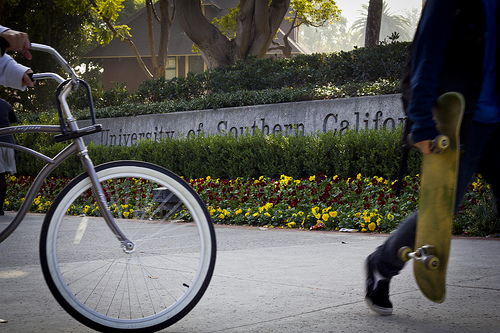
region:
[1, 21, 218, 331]
a person riding a bike at a college university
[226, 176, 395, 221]
a bed of yellow and maroon flowers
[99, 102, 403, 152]
University of Southern California etched into cement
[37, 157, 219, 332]
a bicycle tire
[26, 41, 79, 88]
handlebars on a bicycle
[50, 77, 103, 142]
a bicycle lock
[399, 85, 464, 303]
a skateboard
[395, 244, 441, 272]
wheels on a skateboard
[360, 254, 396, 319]
a young man's tennis shoe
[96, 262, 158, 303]
spokes on a bicycle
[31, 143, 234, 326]
The wheel on a bicycle.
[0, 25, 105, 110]
Handlebars on a bicycle.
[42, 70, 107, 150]
Black u-lock attached to the bicycle.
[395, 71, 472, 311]
Person carrying a skateboard.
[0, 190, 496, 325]
People on the sidewalk.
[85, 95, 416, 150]
The sign says the University of Southern California.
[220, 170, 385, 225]
Flowers growing in the background.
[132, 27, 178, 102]
The trunk of a tree.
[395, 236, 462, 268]
Two wheels on a skateboard.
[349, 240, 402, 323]
The person is wearing a black shoe.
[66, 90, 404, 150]
a concrete sign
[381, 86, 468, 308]
a yellow skateboard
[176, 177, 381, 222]
red flowers in a flower bed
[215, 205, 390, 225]
a row of yellow flowers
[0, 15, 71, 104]
a person's hands on handle bars of a bike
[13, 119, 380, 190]
a row of green hedge bushes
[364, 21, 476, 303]
a person holding a skateboard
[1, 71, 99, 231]
a silver bike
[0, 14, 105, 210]
a person on a bike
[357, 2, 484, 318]
Person carrying a skateboard.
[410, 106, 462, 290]
The wheels on a skateboard.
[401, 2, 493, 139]
Person wearing a dark shirt.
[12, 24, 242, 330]
The front part of a bicycle.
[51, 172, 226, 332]
Spokes on a bicycle tire.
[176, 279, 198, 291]
Valve to inflate bicycle tire.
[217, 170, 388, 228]
Yellow and red flowers.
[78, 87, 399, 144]
A concrete sign in shurbbery.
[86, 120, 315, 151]
The words University of Southern.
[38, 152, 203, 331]
front bike tire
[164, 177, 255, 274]
black and white part of tire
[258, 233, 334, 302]
gray sidewalk near the bike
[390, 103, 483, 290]
skateboard in person's hand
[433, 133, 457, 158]
white wheel of the board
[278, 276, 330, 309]
crack in the sidewalk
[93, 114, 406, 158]
name of the University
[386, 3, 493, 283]
person holding a skateboard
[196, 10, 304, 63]
tree above the sign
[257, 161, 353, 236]
flowers in front of the sign